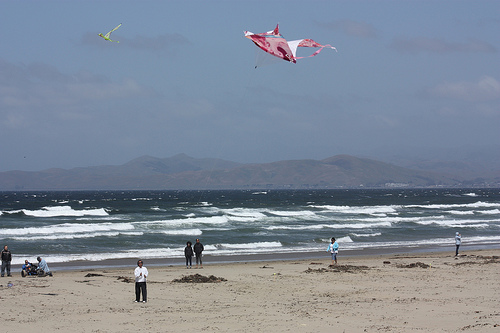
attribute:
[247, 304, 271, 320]
beach — visibley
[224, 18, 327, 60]
kite — large, pink, red, white, big, green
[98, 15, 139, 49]
kite — green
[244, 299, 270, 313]
sand — brown, wet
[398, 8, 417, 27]
sky — blue, clear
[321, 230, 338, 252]
jacket — blue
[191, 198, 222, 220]
ocean — wet